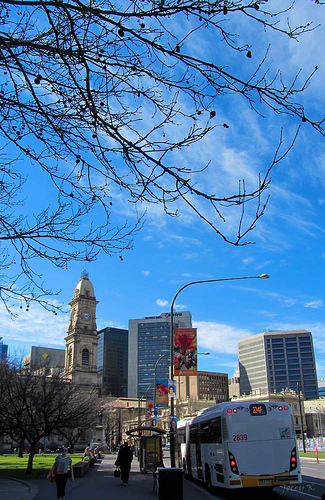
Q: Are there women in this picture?
A: Yes, there is a woman.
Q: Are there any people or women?
A: Yes, there is a woman.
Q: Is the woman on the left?
A: Yes, the woman is on the left of the image.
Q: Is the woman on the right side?
A: No, the woman is on the left of the image.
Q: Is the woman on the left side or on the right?
A: The woman is on the left of the image.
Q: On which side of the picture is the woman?
A: The woman is on the left of the image.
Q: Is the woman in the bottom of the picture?
A: Yes, the woman is in the bottom of the image.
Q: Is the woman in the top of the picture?
A: No, the woman is in the bottom of the image.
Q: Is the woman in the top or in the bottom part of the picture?
A: The woman is in the bottom of the image.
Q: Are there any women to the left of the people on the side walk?
A: Yes, there is a woman to the left of the people.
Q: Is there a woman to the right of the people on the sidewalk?
A: No, the woman is to the left of the people.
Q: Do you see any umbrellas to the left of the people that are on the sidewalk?
A: No, there is a woman to the left of the people.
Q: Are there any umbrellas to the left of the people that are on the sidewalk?
A: No, there is a woman to the left of the people.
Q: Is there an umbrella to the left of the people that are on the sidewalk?
A: No, there is a woman to the left of the people.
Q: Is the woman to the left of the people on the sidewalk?
A: Yes, the woman is to the left of the people.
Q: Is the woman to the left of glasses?
A: No, the woman is to the left of the people.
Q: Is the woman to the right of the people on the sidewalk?
A: No, the woman is to the left of the people.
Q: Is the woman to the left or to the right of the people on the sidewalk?
A: The woman is to the left of the people.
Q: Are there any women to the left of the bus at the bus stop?
A: Yes, there is a woman to the left of the bus.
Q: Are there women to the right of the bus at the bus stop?
A: No, the woman is to the left of the bus.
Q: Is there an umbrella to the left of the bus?
A: No, there is a woman to the left of the bus.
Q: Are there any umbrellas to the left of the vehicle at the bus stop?
A: No, there is a woman to the left of the bus.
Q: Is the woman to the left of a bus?
A: Yes, the woman is to the left of a bus.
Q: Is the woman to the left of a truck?
A: No, the woman is to the left of a bus.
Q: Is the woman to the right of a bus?
A: No, the woman is to the left of a bus.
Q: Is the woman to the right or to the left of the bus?
A: The woman is to the left of the bus.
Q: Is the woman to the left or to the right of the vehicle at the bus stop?
A: The woman is to the left of the bus.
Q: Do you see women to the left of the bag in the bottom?
A: Yes, there is a woman to the left of the bag.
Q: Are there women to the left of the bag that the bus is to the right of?
A: Yes, there is a woman to the left of the bag.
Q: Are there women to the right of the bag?
A: No, the woman is to the left of the bag.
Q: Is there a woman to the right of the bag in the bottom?
A: No, the woman is to the left of the bag.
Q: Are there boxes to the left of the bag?
A: No, there is a woman to the left of the bag.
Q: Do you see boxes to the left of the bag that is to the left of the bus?
A: No, there is a woman to the left of the bag.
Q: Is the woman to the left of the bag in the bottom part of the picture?
A: Yes, the woman is to the left of the bag.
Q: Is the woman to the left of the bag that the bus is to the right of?
A: Yes, the woman is to the left of the bag.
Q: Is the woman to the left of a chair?
A: No, the woman is to the left of the bag.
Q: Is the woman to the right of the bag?
A: No, the woman is to the left of the bag.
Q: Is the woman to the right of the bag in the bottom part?
A: No, the woman is to the left of the bag.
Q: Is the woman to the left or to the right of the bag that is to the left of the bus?
A: The woman is to the left of the bag.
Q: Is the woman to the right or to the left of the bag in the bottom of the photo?
A: The woman is to the left of the bag.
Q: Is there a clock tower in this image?
A: Yes, there is a clock tower.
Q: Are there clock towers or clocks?
A: Yes, there is a clock tower.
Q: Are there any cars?
A: No, there are no cars.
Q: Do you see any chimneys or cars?
A: No, there are no cars or chimneys.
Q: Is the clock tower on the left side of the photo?
A: Yes, the clock tower is on the left of the image.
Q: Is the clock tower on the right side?
A: No, the clock tower is on the left of the image.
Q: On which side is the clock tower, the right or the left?
A: The clock tower is on the left of the image.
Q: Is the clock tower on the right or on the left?
A: The clock tower is on the left of the image.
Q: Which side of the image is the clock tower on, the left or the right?
A: The clock tower is on the left of the image.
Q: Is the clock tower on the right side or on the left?
A: The clock tower is on the left of the image.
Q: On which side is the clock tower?
A: The clock tower is on the left of the image.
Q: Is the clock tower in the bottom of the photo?
A: Yes, the clock tower is in the bottom of the image.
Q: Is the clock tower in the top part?
A: No, the clock tower is in the bottom of the image.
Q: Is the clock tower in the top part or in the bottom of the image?
A: The clock tower is in the bottom of the image.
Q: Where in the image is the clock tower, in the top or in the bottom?
A: The clock tower is in the bottom of the image.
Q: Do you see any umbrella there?
A: No, there are no umbrellas.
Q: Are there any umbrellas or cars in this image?
A: No, there are no umbrellas or cars.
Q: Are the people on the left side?
A: Yes, the people are on the left of the image.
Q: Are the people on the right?
A: No, the people are on the left of the image.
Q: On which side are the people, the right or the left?
A: The people are on the left of the image.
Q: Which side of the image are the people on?
A: The people are on the left of the image.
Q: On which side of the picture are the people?
A: The people are on the left of the image.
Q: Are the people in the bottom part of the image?
A: Yes, the people are in the bottom of the image.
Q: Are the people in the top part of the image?
A: No, the people are in the bottom of the image.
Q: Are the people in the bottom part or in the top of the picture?
A: The people are in the bottom of the image.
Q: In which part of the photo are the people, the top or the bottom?
A: The people are in the bottom of the image.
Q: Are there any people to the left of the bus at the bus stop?
A: Yes, there are people to the left of the bus.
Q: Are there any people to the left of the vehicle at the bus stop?
A: Yes, there are people to the left of the bus.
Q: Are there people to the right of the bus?
A: No, the people are to the left of the bus.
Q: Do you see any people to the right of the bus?
A: No, the people are to the left of the bus.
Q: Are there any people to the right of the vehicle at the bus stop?
A: No, the people are to the left of the bus.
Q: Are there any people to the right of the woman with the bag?
A: Yes, there are people to the right of the woman.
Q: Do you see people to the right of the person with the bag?
A: Yes, there are people to the right of the woman.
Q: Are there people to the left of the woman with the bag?
A: No, the people are to the right of the woman.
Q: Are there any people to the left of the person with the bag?
A: No, the people are to the right of the woman.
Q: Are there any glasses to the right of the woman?
A: No, there are people to the right of the woman.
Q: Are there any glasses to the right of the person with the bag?
A: No, there are people to the right of the woman.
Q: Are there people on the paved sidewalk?
A: Yes, there are people on the sidewalk.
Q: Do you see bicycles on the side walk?
A: No, there are people on the side walk.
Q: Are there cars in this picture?
A: No, there are no cars.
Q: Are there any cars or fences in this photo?
A: No, there are no cars or fences.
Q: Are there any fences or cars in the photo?
A: No, there are no cars or fences.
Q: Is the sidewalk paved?
A: Yes, the sidewalk is paved.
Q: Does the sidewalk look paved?
A: Yes, the sidewalk is paved.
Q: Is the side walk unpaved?
A: No, the side walk is paved.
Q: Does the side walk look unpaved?
A: No, the side walk is paved.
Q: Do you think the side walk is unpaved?
A: No, the side walk is paved.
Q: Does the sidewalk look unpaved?
A: No, the sidewalk is paved.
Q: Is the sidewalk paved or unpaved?
A: The sidewalk is paved.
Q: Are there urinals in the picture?
A: No, there are no urinals.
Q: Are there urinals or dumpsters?
A: No, there are no urinals or dumpsters.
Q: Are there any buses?
A: Yes, there is a bus.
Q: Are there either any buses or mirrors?
A: Yes, there is a bus.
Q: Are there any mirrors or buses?
A: Yes, there is a bus.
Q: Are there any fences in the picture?
A: No, there are no fences.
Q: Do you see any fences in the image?
A: No, there are no fences.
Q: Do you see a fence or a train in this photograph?
A: No, there are no fences or trains.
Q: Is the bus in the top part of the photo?
A: No, the bus is in the bottom of the image.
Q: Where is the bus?
A: The bus is at the bus stop.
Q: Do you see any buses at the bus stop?
A: Yes, there is a bus at the bus stop.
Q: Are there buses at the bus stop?
A: Yes, there is a bus at the bus stop.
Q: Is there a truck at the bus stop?
A: No, there is a bus at the bus stop.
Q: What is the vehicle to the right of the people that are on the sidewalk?
A: The vehicle is a bus.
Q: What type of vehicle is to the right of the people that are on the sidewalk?
A: The vehicle is a bus.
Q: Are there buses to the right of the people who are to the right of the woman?
A: Yes, there is a bus to the right of the people.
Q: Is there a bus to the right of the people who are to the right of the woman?
A: Yes, there is a bus to the right of the people.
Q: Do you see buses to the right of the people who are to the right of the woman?
A: Yes, there is a bus to the right of the people.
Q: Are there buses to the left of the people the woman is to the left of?
A: No, the bus is to the right of the people.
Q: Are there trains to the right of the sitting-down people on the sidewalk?
A: No, there is a bus to the right of the people.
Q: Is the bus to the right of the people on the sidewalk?
A: Yes, the bus is to the right of the people.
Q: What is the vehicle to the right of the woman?
A: The vehicle is a bus.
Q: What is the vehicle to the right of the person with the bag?
A: The vehicle is a bus.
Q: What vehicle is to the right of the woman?
A: The vehicle is a bus.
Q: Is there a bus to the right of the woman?
A: Yes, there is a bus to the right of the woman.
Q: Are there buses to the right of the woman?
A: Yes, there is a bus to the right of the woman.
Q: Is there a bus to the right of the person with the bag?
A: Yes, there is a bus to the right of the woman.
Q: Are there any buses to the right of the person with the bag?
A: Yes, there is a bus to the right of the woman.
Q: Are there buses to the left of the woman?
A: No, the bus is to the right of the woman.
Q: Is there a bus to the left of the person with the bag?
A: No, the bus is to the right of the woman.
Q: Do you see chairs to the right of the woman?
A: No, there is a bus to the right of the woman.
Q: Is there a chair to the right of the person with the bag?
A: No, there is a bus to the right of the woman.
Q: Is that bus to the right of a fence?
A: No, the bus is to the right of a woman.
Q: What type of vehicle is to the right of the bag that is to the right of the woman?
A: The vehicle is a bus.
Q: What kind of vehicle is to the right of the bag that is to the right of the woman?
A: The vehicle is a bus.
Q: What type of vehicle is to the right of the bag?
A: The vehicle is a bus.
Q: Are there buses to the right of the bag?
A: Yes, there is a bus to the right of the bag.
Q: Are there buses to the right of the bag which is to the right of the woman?
A: Yes, there is a bus to the right of the bag.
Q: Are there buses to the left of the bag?
A: No, the bus is to the right of the bag.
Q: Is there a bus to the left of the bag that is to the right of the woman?
A: No, the bus is to the right of the bag.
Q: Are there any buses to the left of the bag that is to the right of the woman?
A: No, the bus is to the right of the bag.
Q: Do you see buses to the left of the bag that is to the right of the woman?
A: No, the bus is to the right of the bag.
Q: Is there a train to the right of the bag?
A: No, there is a bus to the right of the bag.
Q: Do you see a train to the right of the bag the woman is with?
A: No, there is a bus to the right of the bag.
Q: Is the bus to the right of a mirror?
A: No, the bus is to the right of the bag.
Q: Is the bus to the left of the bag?
A: No, the bus is to the right of the bag.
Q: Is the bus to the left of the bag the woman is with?
A: No, the bus is to the right of the bag.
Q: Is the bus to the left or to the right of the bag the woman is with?
A: The bus is to the right of the bag.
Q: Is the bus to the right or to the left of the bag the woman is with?
A: The bus is to the right of the bag.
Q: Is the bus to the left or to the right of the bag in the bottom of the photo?
A: The bus is to the right of the bag.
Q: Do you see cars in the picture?
A: No, there are no cars.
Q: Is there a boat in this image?
A: No, there are no boats.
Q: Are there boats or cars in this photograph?
A: No, there are no boats or cars.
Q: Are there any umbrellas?
A: No, there are no umbrellas.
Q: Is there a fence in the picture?
A: No, there are no fences.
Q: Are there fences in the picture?
A: No, there are no fences.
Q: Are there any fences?
A: No, there are no fences.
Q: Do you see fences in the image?
A: No, there are no fences.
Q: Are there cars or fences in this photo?
A: No, there are no fences or cars.